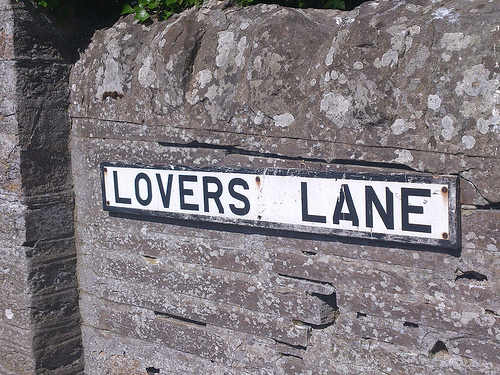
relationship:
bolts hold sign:
[252, 174, 267, 186] [99, 155, 460, 253]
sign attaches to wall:
[99, 155, 460, 253] [79, 17, 488, 358]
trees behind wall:
[114, 0, 211, 20] [79, 17, 488, 358]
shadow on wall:
[27, 9, 116, 65] [79, 17, 488, 358]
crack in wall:
[153, 133, 248, 161] [79, 17, 488, 358]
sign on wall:
[99, 155, 460, 253] [79, 17, 488, 358]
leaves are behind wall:
[107, 0, 287, 16] [79, 17, 488, 358]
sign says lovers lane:
[99, 155, 460, 253] [111, 168, 441, 227]